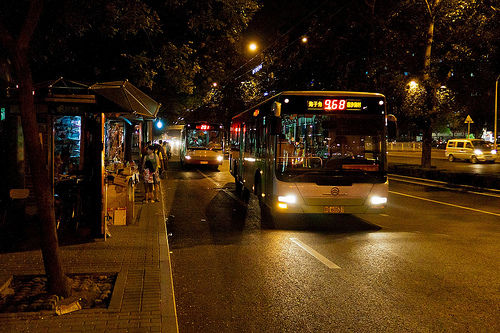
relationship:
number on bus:
[319, 92, 353, 112] [227, 89, 397, 223]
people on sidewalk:
[139, 146, 160, 202] [77, 158, 175, 320]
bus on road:
[227, 89, 397, 223] [160, 137, 497, 329]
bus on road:
[162, 122, 226, 165] [160, 137, 497, 329]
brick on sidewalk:
[0, 170, 172, 331] [0, 141, 177, 331]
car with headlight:
[444, 138, 497, 163] [472, 148, 480, 155]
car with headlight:
[444, 138, 497, 163] [488, 149, 498, 156]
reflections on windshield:
[280, 113, 330, 170] [279, 113, 383, 177]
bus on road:
[225, 88, 397, 224] [162, 155, 499, 331]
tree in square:
[15, 266, 129, 313] [13, 267, 108, 309]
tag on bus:
[321, 203, 346, 216] [227, 89, 397, 223]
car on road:
[444, 138, 497, 163] [160, 137, 497, 329]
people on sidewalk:
[133, 141, 164, 206] [1, 172, 177, 332]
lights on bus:
[354, 188, 401, 233] [217, 69, 418, 240]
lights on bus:
[271, 173, 317, 220] [217, 69, 418, 240]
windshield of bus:
[279, 113, 383, 177] [227, 89, 397, 223]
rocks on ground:
[78, 275, 106, 303] [85, 247, 455, 329]